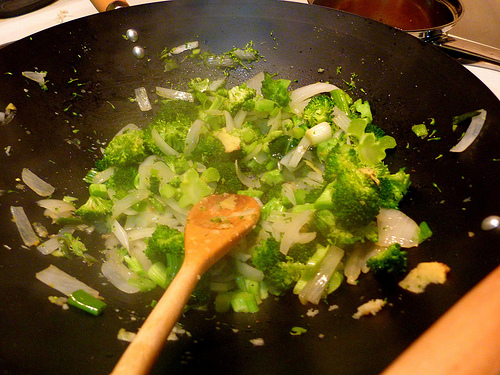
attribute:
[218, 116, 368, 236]
brocolli — green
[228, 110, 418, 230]
brocolli — green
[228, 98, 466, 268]
brocolli — green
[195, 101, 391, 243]
brocolli — green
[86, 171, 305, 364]
spoon — wood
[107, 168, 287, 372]
wood — brown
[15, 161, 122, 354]
onion — glistening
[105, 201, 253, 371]
spoon — wooden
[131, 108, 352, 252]
mixture — broccoli, onions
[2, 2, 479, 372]
wok — black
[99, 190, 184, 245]
onions — chopped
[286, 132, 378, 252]
broccoli — chopped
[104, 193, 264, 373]
spoon — wooden, wood, brown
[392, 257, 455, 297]
vegetable — yellow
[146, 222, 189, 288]
broccoli — green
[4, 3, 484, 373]
skillet — black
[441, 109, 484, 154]
onion — white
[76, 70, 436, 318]
vegetables — green, white, sauted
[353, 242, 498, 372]
table — brown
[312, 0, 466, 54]
pan — metal